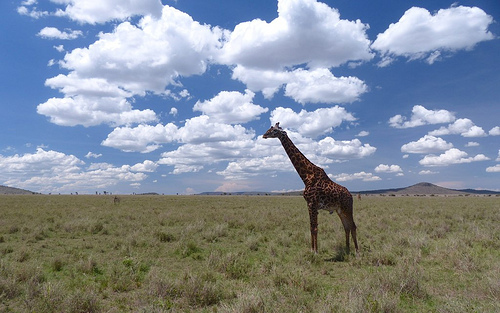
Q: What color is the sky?
A: Blue.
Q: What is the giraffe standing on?
A: Grass.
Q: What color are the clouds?
A: White.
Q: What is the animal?
A: Giraffe.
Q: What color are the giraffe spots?
A: Brown.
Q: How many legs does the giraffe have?
A: Four.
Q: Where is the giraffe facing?
A: Left.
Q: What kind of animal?
A: Giraffe.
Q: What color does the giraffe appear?
A: Brown.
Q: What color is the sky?
A: Blue.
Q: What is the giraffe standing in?
A: Grass.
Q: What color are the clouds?
A: White.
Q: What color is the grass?
A: Green.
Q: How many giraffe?
A: One.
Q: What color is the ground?
A: Brown and green.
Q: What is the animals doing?
A: Standing.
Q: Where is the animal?
A: In the field.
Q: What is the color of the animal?
A: Brown and white.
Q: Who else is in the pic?
A: No one.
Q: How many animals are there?
A: 1.